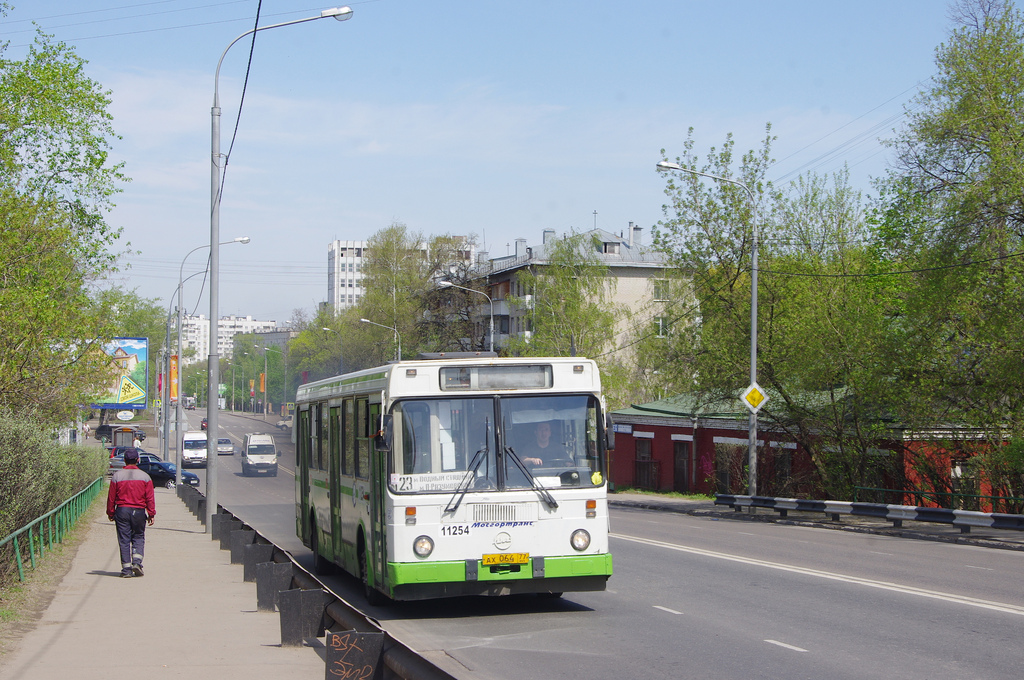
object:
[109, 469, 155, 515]
jacket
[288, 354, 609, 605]
bus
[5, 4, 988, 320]
sky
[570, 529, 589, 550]
headlight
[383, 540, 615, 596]
bumper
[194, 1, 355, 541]
street light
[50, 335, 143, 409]
billboard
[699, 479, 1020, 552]
road barrier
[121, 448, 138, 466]
head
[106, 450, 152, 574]
man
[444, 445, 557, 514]
windshield wipers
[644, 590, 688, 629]
line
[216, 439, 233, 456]
car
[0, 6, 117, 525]
tree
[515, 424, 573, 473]
driver